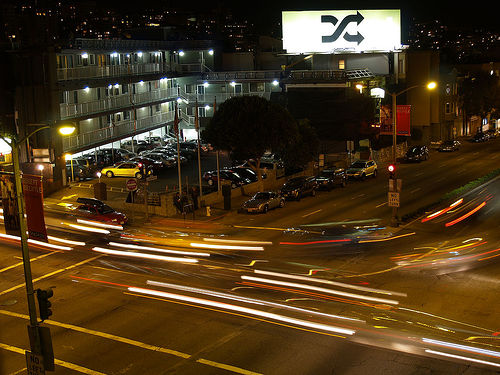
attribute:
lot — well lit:
[66, 134, 302, 199]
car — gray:
[242, 190, 286, 213]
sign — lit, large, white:
[282, 9, 401, 54]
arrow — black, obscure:
[321, 11, 364, 43]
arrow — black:
[343, 30, 365, 44]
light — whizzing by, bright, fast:
[76, 217, 124, 231]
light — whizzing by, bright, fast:
[189, 241, 264, 251]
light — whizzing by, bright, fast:
[108, 241, 210, 258]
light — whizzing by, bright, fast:
[253, 268, 407, 298]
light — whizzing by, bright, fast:
[47, 234, 86, 246]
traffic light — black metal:
[36, 287, 54, 319]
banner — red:
[21, 173, 50, 242]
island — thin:
[372, 169, 499, 237]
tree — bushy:
[199, 94, 294, 192]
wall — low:
[196, 169, 310, 208]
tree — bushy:
[272, 115, 320, 176]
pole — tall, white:
[174, 100, 182, 194]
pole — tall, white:
[195, 96, 203, 197]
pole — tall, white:
[214, 94, 221, 193]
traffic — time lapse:
[1, 178, 500, 368]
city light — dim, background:
[420, 30, 424, 34]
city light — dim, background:
[144, 22, 160, 27]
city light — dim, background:
[97, 33, 103, 38]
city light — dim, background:
[42, 13, 47, 17]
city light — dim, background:
[435, 20, 440, 24]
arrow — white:
[58, 194, 78, 201]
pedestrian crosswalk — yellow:
[1, 230, 121, 293]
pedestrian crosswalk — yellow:
[0, 309, 265, 374]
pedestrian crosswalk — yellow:
[213, 220, 322, 233]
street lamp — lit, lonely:
[56, 125, 76, 136]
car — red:
[70, 202, 127, 228]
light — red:
[388, 165, 394, 171]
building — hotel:
[9, 34, 374, 183]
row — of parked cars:
[243, 128, 499, 212]